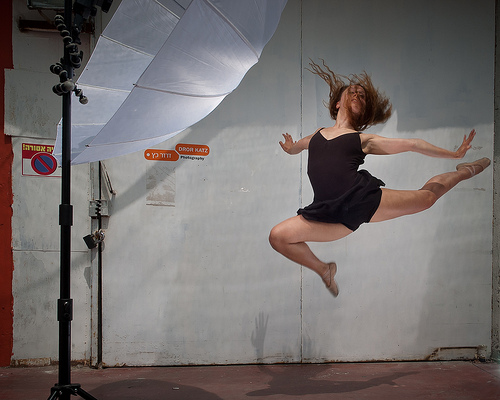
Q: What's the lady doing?
A: Jumping.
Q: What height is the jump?
A: 2.5 feet.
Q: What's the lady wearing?
A: Black dress.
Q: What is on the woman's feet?
A: Ballet slippers.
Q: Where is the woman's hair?
A: In the air.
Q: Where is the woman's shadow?
A: On the ground.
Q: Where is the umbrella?
A: Attached to the pole.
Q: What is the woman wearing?
A: A black dress.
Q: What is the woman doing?
A: Leaping.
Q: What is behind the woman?
A: White wall.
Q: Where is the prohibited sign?
A: On the wall behind the light pole.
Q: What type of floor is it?
A: Cement.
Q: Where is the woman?
A: In the air.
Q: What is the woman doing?
A: Jumping.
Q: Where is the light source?
A: On the pole.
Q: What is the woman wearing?
A: Black dress.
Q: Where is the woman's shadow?
A: On the ground.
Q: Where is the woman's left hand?
A: Near her left foot.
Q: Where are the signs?
A: On the wall.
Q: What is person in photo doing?
A: Jumping.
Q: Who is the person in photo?
A: Woman.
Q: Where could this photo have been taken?
A: Photography studio.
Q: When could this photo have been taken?
A: Morning.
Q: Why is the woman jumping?
A: Dancing.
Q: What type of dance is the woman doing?
A: Ballet.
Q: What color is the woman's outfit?
A: Black.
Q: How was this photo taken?
A: Camera.